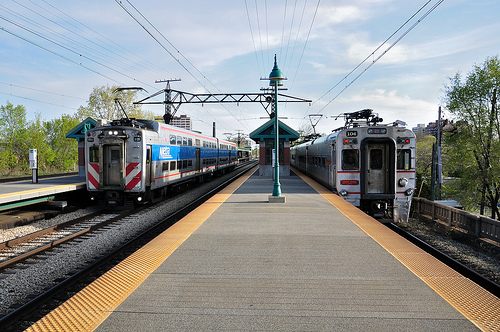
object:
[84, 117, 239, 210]
train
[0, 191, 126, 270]
tracks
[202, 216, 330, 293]
platform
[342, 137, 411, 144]
lights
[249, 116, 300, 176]
hut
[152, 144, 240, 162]
stripes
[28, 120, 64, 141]
leaves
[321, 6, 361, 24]
clouds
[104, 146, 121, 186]
door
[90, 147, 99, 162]
window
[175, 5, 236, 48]
sky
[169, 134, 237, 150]
windows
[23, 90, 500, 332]
station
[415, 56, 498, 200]
bushes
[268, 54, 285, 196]
post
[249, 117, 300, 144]
covering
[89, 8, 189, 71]
wires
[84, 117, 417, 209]
trains